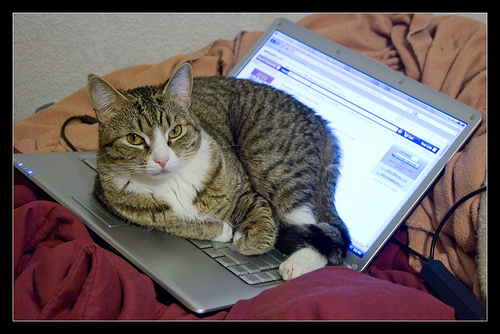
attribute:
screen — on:
[218, 27, 481, 283]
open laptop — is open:
[12, 17, 482, 313]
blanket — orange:
[12, 12, 478, 282]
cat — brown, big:
[80, 59, 353, 269]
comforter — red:
[13, 148, 453, 318]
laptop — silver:
[79, 21, 499, 321]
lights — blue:
[10, 155, 34, 179]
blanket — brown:
[17, 20, 474, 329]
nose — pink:
[153, 148, 172, 167]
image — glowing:
[237, 36, 466, 249]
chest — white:
[108, 133, 228, 223]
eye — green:
[121, 125, 151, 151]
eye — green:
[164, 119, 190, 142]